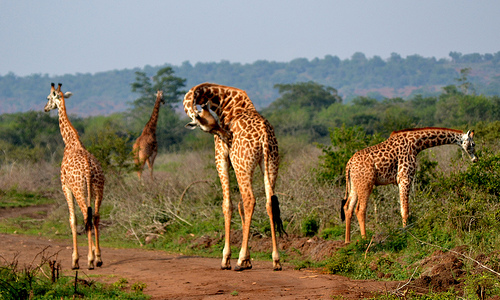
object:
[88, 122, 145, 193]
full bush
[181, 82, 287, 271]
giraffe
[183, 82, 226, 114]
neck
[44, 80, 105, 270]
giraffe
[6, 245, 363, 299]
dirt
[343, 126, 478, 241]
giraffe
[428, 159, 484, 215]
grass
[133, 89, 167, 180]
giraffe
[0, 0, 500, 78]
sky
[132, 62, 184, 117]
tree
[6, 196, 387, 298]
trail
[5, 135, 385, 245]
grass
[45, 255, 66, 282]
twig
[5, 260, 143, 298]
grass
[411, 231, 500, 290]
stick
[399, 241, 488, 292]
dirt